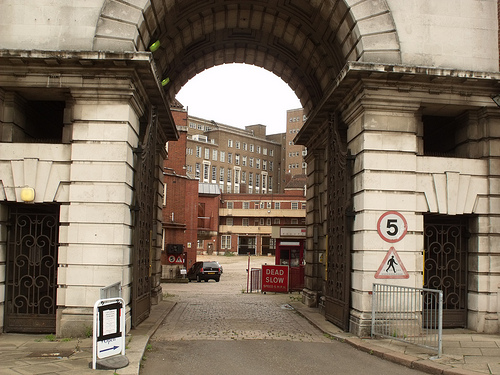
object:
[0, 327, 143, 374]
sidewalk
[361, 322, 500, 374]
sidewalk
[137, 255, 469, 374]
street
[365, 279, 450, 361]
barrier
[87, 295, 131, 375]
sign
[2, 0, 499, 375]
building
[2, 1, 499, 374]
outdoors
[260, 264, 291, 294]
sign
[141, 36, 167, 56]
lights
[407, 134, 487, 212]
ground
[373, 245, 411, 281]
sign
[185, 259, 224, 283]
vehicle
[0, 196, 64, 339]
gate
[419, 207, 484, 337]
gate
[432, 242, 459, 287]
iron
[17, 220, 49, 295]
iron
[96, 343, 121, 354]
arrow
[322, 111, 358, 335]
gate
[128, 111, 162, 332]
gate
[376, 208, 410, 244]
sign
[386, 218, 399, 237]
5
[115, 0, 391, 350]
arch